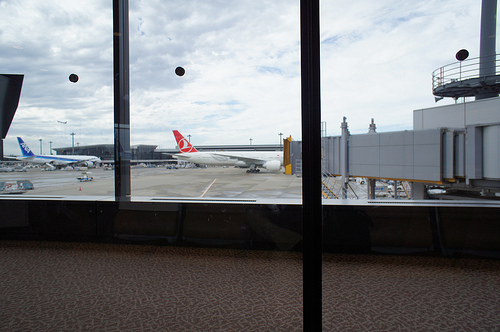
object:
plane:
[162, 130, 284, 174]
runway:
[0, 165, 365, 201]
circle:
[174, 67, 186, 77]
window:
[131, 1, 303, 205]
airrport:
[1, 137, 103, 172]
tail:
[172, 130, 200, 153]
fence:
[324, 131, 464, 184]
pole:
[340, 116, 350, 199]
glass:
[0, 0, 496, 207]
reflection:
[2, 201, 499, 255]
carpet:
[0, 238, 500, 331]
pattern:
[61, 259, 239, 298]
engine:
[262, 160, 281, 171]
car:
[76, 172, 94, 182]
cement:
[1, 169, 359, 200]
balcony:
[431, 54, 500, 98]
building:
[413, 98, 499, 182]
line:
[199, 179, 217, 199]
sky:
[0, 2, 499, 150]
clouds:
[2, 1, 477, 153]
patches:
[209, 8, 418, 115]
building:
[52, 144, 180, 167]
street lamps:
[70, 132, 76, 155]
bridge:
[154, 145, 286, 154]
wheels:
[246, 169, 258, 172]